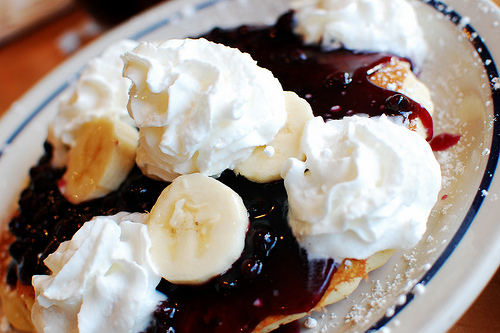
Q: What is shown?
A: A pancake.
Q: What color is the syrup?
A: Red.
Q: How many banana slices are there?
A: Three.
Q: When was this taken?
A: In the daytime.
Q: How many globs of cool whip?
A: Five.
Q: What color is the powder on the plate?
A: White.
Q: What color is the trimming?
A: Blue.